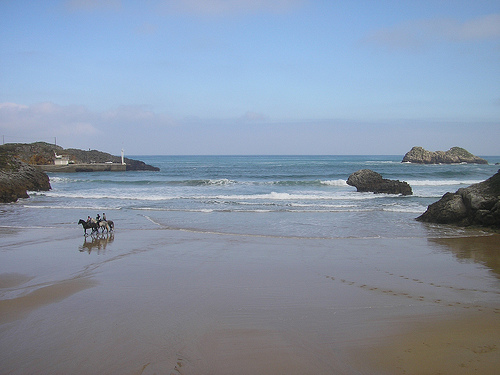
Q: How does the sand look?
A: Wet.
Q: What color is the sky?
A: Blue.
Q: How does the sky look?
A: Clear.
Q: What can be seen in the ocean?
A: A wave.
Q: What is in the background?
A: Mountains.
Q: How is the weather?
A: Cloudy.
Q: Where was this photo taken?
A: Beach.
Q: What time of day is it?
A: Daytime.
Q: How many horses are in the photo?
A: 3.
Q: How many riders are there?
A: 3.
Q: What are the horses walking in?
A: Sand.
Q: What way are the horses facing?
A: Left.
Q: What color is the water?
A: Blue.